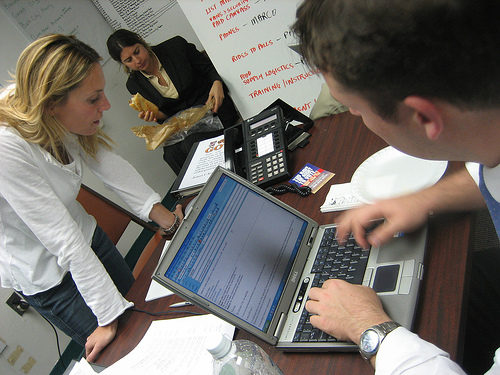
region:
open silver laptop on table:
[146, 158, 438, 363]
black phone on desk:
[212, 92, 324, 200]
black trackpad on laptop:
[366, 259, 406, 296]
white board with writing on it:
[172, 0, 379, 129]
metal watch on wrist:
[336, 315, 401, 370]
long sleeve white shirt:
[0, 80, 166, 335]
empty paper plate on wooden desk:
[342, 133, 458, 203]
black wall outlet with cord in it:
[2, 284, 79, 374]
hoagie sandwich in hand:
[114, 90, 166, 122]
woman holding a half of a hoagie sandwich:
[93, 22, 240, 184]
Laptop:
[152, 166, 429, 351]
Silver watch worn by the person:
[355, 321, 402, 365]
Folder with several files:
[168, 133, 232, 198]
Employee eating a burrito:
[104, 23, 245, 171]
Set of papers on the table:
[62, 311, 239, 373]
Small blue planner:
[287, 163, 335, 198]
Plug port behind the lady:
[7, 292, 65, 372]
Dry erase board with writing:
[174, 1, 345, 128]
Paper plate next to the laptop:
[352, 145, 449, 197]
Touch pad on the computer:
[364, 259, 415, 299]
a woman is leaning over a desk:
[1, 35, 188, 370]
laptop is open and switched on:
[149, 161, 434, 359]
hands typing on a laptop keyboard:
[289, 190, 430, 360]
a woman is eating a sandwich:
[104, 23, 249, 183]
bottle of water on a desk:
[197, 326, 288, 373]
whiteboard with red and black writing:
[185, 0, 365, 136]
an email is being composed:
[158, 163, 320, 360]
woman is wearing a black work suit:
[105, 25, 242, 185]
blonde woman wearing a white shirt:
[0, 30, 187, 365]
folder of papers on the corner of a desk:
[168, 133, 244, 205]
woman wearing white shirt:
[10, 36, 158, 366]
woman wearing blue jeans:
[15, 32, 137, 343]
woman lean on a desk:
[0, 30, 145, 340]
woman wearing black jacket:
[100, 23, 210, 129]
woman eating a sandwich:
[101, 31, 221, 136]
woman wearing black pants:
[100, 27, 227, 132]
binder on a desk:
[166, 138, 207, 190]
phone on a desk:
[236, 115, 288, 178]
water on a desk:
[201, 330, 271, 368]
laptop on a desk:
[188, 174, 298, 312]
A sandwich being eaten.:
[127, 90, 158, 116]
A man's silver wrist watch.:
[352, 315, 397, 360]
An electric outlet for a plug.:
[5, 292, 30, 317]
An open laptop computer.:
[150, 162, 427, 347]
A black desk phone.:
[220, 105, 290, 185]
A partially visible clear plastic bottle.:
[205, 330, 275, 370]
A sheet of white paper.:
[109, 313, 235, 373]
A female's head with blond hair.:
[0, 30, 106, 145]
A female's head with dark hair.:
[105, 25, 155, 72]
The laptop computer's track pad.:
[371, 260, 401, 295]